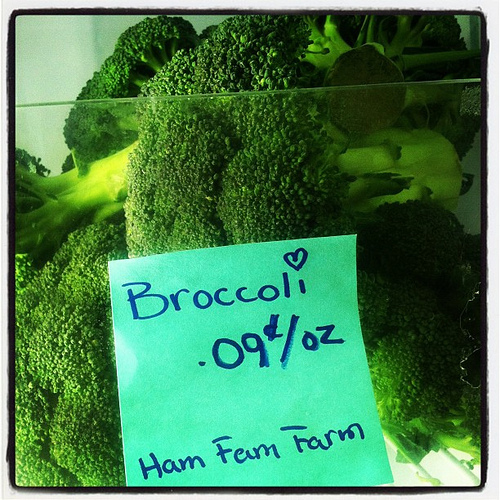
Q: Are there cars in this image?
A: No, there are no cars.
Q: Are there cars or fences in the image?
A: No, there are no cars or fences.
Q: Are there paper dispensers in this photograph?
A: No, there are no paper dispensers.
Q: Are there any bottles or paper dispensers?
A: No, there are no paper dispensers or bottles.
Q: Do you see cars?
A: No, there are no cars.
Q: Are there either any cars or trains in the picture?
A: No, there are no cars or trains.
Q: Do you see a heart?
A: Yes, there is a heart.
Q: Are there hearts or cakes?
A: Yes, there is a heart.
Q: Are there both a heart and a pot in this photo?
A: No, there is a heart but no pots.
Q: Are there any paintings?
A: No, there are no paintings.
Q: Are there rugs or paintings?
A: No, there are no paintings or rugs.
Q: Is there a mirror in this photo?
A: No, there are no mirrors.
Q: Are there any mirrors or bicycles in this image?
A: No, there are no mirrors or bicycles.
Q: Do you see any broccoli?
A: Yes, there is broccoli.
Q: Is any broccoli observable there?
A: Yes, there is broccoli.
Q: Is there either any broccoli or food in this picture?
A: Yes, there is broccoli.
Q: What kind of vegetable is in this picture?
A: The vegetable is broccoli.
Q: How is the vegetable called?
A: The vegetable is broccoli.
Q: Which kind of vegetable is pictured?
A: The vegetable is broccoli.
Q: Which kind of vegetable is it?
A: The vegetable is broccoli.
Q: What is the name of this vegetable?
A: This is broccoli.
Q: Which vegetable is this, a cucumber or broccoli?
A: This is broccoli.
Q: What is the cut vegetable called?
A: The vegetable is broccoli.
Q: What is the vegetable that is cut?
A: The vegetable is broccoli.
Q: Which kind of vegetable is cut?
A: The vegetable is broccoli.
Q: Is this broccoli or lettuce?
A: This is broccoli.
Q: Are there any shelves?
A: No, there are no shelves.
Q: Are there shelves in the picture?
A: No, there are no shelves.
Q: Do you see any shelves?
A: No, there are no shelves.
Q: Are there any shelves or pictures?
A: No, there are no shelves or pictures.